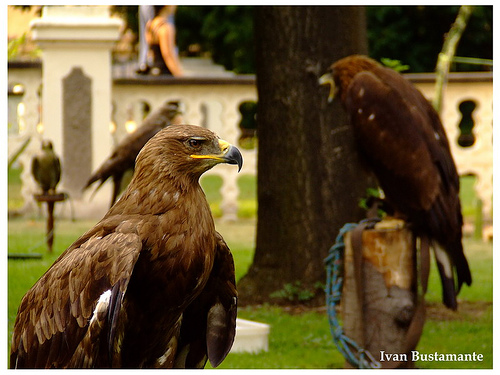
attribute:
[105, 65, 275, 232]
wall — low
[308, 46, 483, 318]
bird — brown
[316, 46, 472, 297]
bird — brown, with its mouth open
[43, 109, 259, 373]
falcon — brown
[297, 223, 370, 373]
cord — woven, blue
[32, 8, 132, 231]
pillar — white, grey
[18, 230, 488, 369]
grass — green, lush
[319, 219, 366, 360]
cord — blue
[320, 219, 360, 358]
cord — blue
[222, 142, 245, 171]
beak — black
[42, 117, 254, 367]
bird — brown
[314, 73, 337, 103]
mouth — white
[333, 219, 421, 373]
tree stump — brown, large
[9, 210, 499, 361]
grass — green, manicured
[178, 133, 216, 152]
eye — black, slanted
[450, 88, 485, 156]
design — beautiful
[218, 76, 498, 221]
fence — pink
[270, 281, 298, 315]
branch — small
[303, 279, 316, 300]
branch — small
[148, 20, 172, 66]
shirt — long sleeve, orange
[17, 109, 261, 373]
bird — brown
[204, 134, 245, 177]
beak — yellow, black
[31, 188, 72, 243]
stand — wooden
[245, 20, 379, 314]
tree trunk — in the background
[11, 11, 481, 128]
wall — in the background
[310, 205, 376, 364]
rope — blue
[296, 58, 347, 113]
bird — with an open 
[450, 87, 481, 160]
wall — opening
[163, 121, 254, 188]
bird's peak — sharp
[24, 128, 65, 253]
bird — facing forward on perch.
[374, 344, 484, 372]
name — in right corner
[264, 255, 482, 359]
grass — green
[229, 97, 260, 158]
opening — in far wall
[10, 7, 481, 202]
white structure — behind bird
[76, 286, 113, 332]
white feather — on bird's wing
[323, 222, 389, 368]
blue cord — hanging over post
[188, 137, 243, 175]
bird's beak — yellow and black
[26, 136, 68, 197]
bird — in the distance